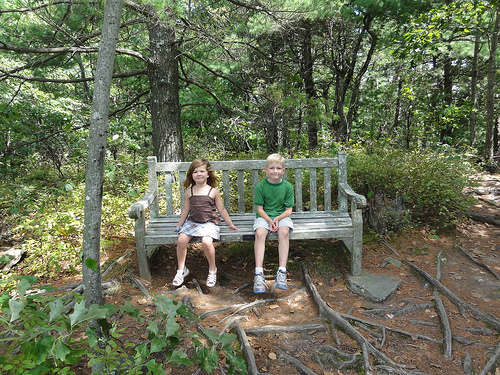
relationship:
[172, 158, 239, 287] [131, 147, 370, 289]
child sitting on bench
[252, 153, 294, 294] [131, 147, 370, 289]
boy sitting on bench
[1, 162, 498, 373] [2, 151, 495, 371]
roots on ground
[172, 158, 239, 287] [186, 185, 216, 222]
child wearing top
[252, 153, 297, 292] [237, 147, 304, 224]
boy wearing t-shirt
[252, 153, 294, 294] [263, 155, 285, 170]
boy has hair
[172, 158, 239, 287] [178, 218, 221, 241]
child in skirt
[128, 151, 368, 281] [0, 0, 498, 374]
bench in forest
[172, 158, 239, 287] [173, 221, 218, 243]
child wearing skirt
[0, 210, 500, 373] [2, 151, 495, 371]
roots above ground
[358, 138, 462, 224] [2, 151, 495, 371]
bushes on ground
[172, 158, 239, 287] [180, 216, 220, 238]
child wearing skirt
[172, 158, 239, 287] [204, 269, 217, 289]
child wearing sandal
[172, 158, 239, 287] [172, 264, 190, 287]
child wearing sandal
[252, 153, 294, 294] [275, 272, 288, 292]
boy has foot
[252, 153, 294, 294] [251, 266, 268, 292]
boy has feet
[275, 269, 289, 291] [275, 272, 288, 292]
shoe on foot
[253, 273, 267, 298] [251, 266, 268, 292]
shoe on feet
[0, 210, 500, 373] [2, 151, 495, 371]
roots growing in ground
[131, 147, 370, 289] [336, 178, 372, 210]
bench has arm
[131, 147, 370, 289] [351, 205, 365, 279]
bench has leg